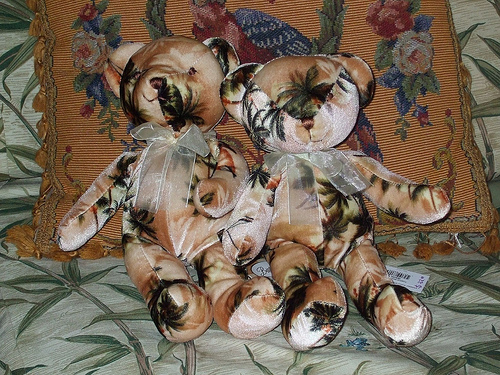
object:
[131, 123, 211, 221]
bow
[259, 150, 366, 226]
bow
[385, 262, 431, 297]
tag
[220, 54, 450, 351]
bear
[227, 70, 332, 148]
print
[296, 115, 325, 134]
nose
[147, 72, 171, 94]
nose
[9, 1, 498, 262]
pillow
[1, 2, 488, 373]
blanket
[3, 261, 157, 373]
print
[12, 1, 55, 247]
tassles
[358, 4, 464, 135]
pattern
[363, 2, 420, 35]
flowers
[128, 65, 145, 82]
eyes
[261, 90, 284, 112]
eyes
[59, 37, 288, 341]
bear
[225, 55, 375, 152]
face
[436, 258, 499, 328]
green leaves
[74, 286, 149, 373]
brown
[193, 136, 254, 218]
arms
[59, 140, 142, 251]
arms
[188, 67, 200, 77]
eye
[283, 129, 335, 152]
mouth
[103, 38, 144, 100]
ear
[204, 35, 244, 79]
ear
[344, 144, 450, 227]
arm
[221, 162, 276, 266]
arm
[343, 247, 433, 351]
leg